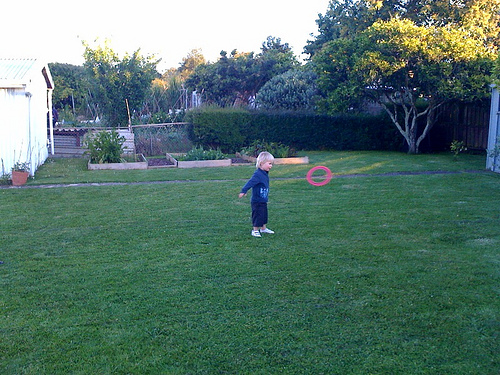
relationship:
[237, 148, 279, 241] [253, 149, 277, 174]
boy has head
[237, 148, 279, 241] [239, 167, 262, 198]
boy has arm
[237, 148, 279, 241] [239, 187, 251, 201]
boy has hand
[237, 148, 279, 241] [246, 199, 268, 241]
boy has leg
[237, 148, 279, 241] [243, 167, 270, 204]
boy has shirt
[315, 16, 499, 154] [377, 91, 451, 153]
tree has trunk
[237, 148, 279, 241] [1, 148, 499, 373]
boy on grass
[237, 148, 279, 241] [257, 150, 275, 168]
boy has hair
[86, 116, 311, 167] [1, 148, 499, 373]
graden on grass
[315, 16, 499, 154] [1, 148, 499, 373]
tree on grass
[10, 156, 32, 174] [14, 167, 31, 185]
plant in pot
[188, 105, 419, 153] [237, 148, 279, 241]
bush behind boy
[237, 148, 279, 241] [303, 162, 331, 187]
boy throwing disc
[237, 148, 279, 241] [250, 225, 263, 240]
boy wearing shoe